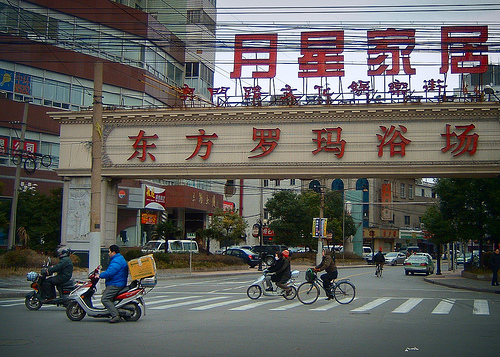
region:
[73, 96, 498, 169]
Asian writing on an arch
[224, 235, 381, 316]
bicycles on a cross walk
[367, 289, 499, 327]
white stripes on the road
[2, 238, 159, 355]
scooters on the road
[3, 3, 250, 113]
Building with lots of windows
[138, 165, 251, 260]
store front with signs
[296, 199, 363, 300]
street lights next to the road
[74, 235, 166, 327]
package on the back of the scooter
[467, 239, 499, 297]
person walking on the sidewalk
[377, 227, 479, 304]
vehicles driving on the road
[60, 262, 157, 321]
a silver motorcycle in stret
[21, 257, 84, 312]
a motorcycle in street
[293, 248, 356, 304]
a man riding bicycle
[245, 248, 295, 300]
a man riding bicycle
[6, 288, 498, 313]
a painted pedestrian crosswalk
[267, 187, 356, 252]
a large green tree in distance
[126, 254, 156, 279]
a large yellow box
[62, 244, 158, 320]
a man riding a motorcycle with package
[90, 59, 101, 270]
a tall brown telephone pole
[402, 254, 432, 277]
a parked green car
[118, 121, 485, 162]
Red oriental writing on over top of structure.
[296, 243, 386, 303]
A couple of people on bicycles.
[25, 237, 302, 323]
Four people on scooters.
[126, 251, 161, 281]
A cardboard box for carrying items.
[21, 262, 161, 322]
Red and Silver scooters.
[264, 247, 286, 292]
A person with a mask for protection.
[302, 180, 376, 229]
Blue arches on a building.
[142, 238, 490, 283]
Four wheel vehicles in the background.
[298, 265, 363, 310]
Green bag on bicycle for carrying items.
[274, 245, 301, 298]
Red cap on person to protect head.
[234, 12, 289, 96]
part of a grpahic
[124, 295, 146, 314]
part of a wheel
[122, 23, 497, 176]
Asian writing on structure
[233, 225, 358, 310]
People on bikes crossing street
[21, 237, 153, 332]
People riding scooters in street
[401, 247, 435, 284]
A car near curb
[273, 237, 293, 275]
Person is wearing an orange stocking cap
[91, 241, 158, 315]
Box on the back of scooter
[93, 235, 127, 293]
Man wearing a blue coat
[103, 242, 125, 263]
Not wearing a helmet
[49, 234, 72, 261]
Person wearing helmet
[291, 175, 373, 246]
Traffic signals are on poles